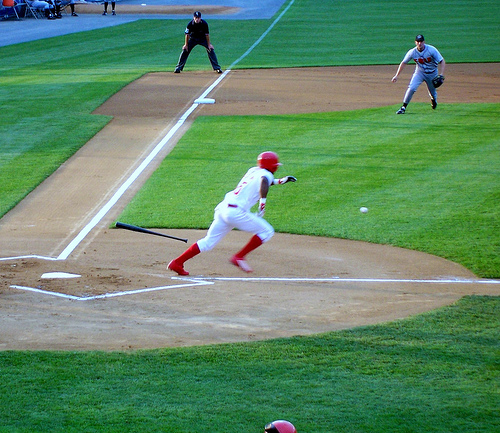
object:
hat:
[411, 34, 427, 42]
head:
[412, 33, 425, 52]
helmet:
[256, 149, 286, 174]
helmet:
[263, 414, 300, 432]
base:
[36, 270, 79, 279]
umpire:
[173, 12, 223, 73]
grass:
[0, 293, 498, 430]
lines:
[114, 67, 229, 199]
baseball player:
[165, 149, 299, 282]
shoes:
[167, 258, 196, 277]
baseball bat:
[108, 219, 185, 245]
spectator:
[0, 0, 16, 20]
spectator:
[33, 0, 61, 19]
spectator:
[103, 1, 117, 15]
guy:
[386, 33, 443, 116]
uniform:
[402, 46, 446, 114]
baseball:
[358, 205, 370, 214]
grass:
[113, 1, 498, 72]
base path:
[111, 253, 499, 294]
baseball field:
[0, 1, 499, 430]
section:
[2, 209, 484, 351]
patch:
[54, 377, 128, 433]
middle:
[0, 238, 207, 306]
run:
[169, 143, 302, 278]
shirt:
[182, 23, 212, 50]